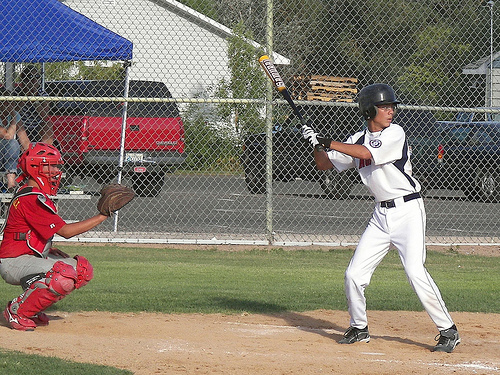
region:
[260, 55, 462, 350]
Batter getting ready to swing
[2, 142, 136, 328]
Catcher ready for pitch behind batter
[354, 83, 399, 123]
Helmet on the batters head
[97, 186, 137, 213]
Glove on the catchers hand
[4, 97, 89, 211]
Stands for the people watching baseball game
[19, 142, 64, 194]
Helmet on the catcher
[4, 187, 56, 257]
protective chest gear on catcher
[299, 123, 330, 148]
Gloves on the batter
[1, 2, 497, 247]
Fence behind baseball players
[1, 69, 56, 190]
People watching baseball game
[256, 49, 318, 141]
a black baseball bat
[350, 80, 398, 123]
a black baseball helmet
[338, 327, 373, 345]
a boy's black tennis shoe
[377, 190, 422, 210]
part of a boy's black belt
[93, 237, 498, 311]
a section of green grass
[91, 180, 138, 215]
a brown baseball glove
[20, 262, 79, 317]
a red leg pad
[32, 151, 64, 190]
a red face mask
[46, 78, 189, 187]
part of a large red suv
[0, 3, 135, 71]
part of a blue tent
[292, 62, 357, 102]
stack of brown wooden pallets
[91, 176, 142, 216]
brown leather baseball glove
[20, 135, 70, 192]
catcher in red safety helmet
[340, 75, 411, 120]
black hard plastic safety helmet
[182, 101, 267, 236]
grey metal chain length fencing behind players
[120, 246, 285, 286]
baseball field covered in green grass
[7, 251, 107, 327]
red knee guards on baseball catcher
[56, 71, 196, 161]
red vehicle parked beside baseball field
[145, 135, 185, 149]
company name on back of vehicle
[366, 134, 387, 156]
team logo on sleeve of shirt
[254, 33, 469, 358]
a baseball player holds a bat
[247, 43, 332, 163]
a wood bat with letters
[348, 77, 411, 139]
a baseball helmet color black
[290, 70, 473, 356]
player wears white clothes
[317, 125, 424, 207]
shirt has black stripes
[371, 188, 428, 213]
a black belt on white pants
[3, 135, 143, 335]
catcher has a brown glove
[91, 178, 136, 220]
glove is color brown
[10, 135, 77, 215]
helmet of catcher is color red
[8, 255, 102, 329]
guard shins of catcher are red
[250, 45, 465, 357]
Boy swinging a baseball bat.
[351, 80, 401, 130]
Black helmet on the boy.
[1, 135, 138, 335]
Catcher playing baseball.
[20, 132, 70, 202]
Red face mask on catcher.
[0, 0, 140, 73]
Blue canopy behind the fence,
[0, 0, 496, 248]
chain link fence in the background.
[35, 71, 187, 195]
Red truck behind the fence.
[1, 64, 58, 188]
People watching the game.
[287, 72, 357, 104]
Wooden pallets in the background.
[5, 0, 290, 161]
House in the background.